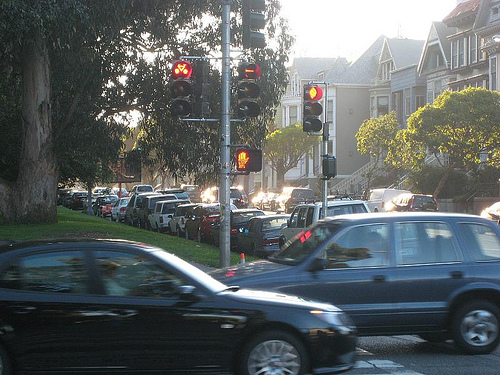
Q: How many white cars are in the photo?
A: Five.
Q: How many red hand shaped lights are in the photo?
A: One.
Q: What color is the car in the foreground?
A: Black.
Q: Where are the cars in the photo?
A: Street.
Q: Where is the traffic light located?
A: Corner.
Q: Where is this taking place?
A: On the street.